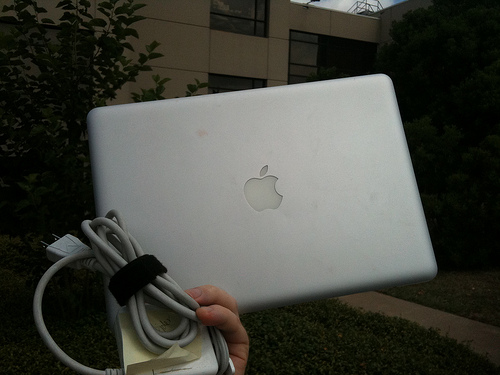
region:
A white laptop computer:
[78, 57, 464, 329]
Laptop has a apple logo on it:
[219, 145, 302, 226]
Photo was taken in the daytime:
[8, 4, 498, 358]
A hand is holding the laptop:
[133, 265, 271, 373]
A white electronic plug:
[18, 208, 200, 373]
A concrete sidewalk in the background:
[362, 286, 498, 372]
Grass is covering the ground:
[0, 312, 422, 373]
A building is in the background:
[1, 2, 423, 212]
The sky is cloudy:
[299, 2, 407, 25]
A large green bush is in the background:
[386, 10, 499, 266]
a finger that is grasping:
[198, 305, 251, 370]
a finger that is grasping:
[185, 281, 237, 318]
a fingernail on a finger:
[197, 306, 210, 313]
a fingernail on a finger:
[188, 283, 200, 293]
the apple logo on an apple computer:
[241, 160, 280, 212]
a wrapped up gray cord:
[30, 207, 208, 372]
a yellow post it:
[116, 302, 201, 365]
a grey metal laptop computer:
[78, 72, 438, 318]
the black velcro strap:
[110, 254, 160, 296]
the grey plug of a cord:
[38, 231, 90, 265]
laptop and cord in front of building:
[22, 60, 470, 351]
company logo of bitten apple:
[211, 125, 306, 235]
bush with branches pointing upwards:
[5, 2, 225, 162]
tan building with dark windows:
[96, 2, 362, 73]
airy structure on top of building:
[320, 0, 400, 20]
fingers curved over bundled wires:
[67, 180, 247, 365]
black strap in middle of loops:
[75, 195, 201, 355]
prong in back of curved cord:
[31, 201, 96, 286]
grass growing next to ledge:
[252, 302, 482, 359]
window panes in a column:
[276, 7, 332, 85]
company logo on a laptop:
[220, 156, 294, 226]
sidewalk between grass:
[339, 294, 499, 360]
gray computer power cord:
[40, 207, 215, 374]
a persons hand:
[182, 272, 259, 373]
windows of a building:
[205, 0, 284, 36]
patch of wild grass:
[295, 316, 379, 361]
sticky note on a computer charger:
[107, 303, 207, 368]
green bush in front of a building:
[5, 5, 141, 230]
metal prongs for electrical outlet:
[34, 227, 66, 255]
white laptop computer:
[70, 71, 449, 313]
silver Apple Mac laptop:
[67, 73, 441, 328]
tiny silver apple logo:
[235, 155, 293, 218]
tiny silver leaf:
[256, 163, 273, 177]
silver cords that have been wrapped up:
[21, 209, 259, 374]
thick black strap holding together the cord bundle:
[109, 246, 171, 316]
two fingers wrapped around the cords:
[178, 271, 265, 371]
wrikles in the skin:
[227, 337, 249, 364]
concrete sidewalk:
[331, 283, 499, 365]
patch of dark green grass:
[235, 302, 481, 373]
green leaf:
[147, 50, 167, 62]